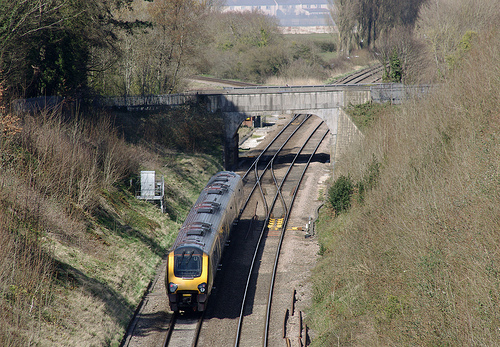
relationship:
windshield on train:
[176, 256, 199, 272] [164, 171, 246, 315]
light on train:
[200, 286, 206, 293] [164, 171, 246, 315]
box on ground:
[140, 170, 156, 197] [0, 33, 499, 346]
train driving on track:
[164, 171, 246, 315] [216, 66, 398, 347]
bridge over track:
[23, 86, 441, 172] [216, 66, 398, 347]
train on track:
[164, 171, 246, 315] [216, 66, 398, 347]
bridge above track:
[23, 86, 441, 172] [216, 66, 398, 347]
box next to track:
[140, 170, 156, 197] [216, 66, 398, 347]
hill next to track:
[308, 29, 500, 346] [216, 66, 398, 347]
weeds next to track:
[0, 113, 222, 346] [216, 66, 398, 347]